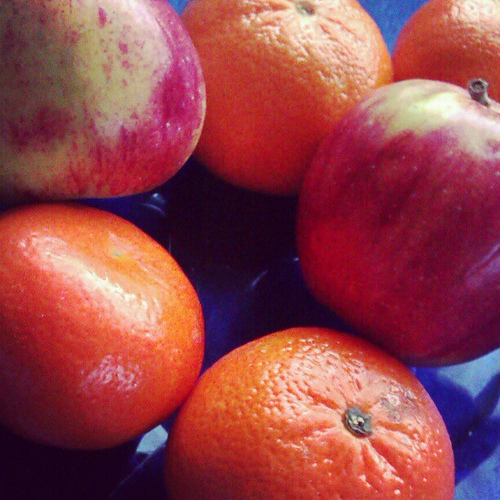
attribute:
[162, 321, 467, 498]
orange — ripe, a fruit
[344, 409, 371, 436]
dimple — small, brown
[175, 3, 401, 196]
orange — ripe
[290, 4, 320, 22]
dimple — small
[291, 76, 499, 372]
apple — red, yellow, a fruit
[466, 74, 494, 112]
stem — dark brown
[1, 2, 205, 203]
apple — yellow, light red, red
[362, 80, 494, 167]
patch — yellow